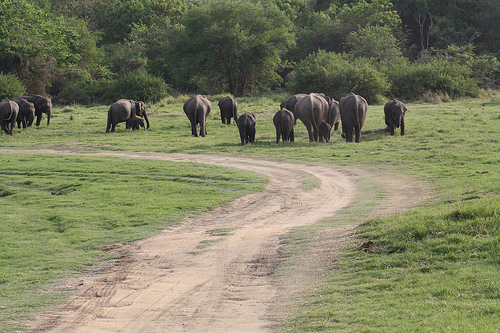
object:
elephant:
[382, 96, 408, 137]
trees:
[5, 4, 499, 105]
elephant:
[216, 93, 238, 125]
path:
[0, 144, 430, 331]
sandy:
[0, 140, 438, 327]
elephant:
[106, 99, 150, 134]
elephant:
[183, 93, 212, 137]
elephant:
[234, 111, 257, 147]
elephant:
[272, 108, 297, 143]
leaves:
[0, 0, 63, 53]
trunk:
[45, 108, 52, 124]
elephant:
[20, 94, 52, 126]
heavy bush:
[279, 46, 386, 100]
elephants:
[235, 112, 258, 146]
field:
[4, 92, 499, 329]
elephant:
[338, 93, 369, 142]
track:
[8, 137, 424, 331]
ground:
[2, 92, 498, 332]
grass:
[1, 94, 499, 330]